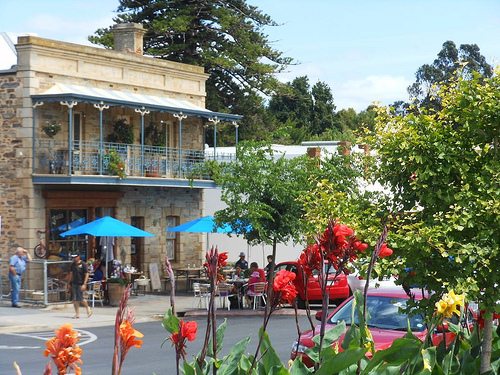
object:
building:
[0, 20, 211, 309]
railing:
[35, 138, 144, 178]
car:
[289, 287, 481, 374]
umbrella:
[60, 215, 158, 239]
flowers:
[376, 241, 393, 259]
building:
[30, 80, 245, 182]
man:
[64, 249, 94, 320]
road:
[187, 316, 295, 357]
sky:
[295, 5, 415, 71]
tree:
[409, 40, 492, 123]